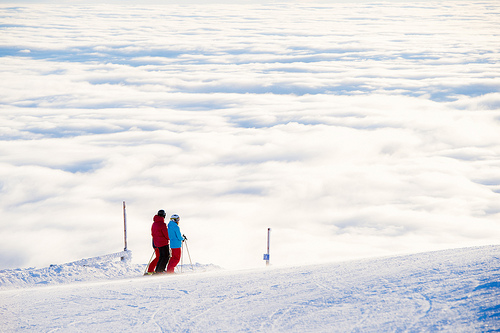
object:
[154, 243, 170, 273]
pants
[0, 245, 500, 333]
ground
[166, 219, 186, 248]
blue jacket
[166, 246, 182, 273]
pants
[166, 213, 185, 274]
person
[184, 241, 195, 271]
pole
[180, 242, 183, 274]
pole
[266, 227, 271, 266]
pole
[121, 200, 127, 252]
pole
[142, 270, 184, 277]
ski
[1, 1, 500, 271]
clouds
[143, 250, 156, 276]
poles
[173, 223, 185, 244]
sleeve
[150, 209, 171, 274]
man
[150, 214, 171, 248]
coat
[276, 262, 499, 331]
tracks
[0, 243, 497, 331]
snow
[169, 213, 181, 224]
helmet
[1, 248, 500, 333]
mountain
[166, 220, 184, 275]
outfit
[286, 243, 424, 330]
run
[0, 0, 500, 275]
sky